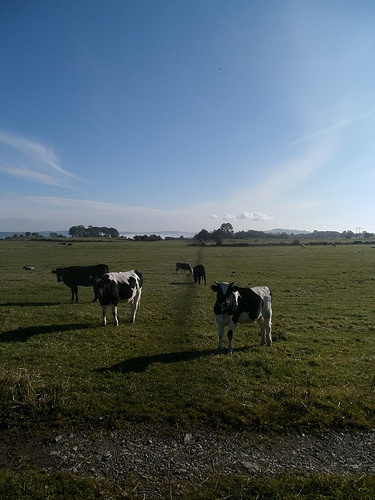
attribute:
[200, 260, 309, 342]
cow — black, white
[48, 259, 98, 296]
cow — black